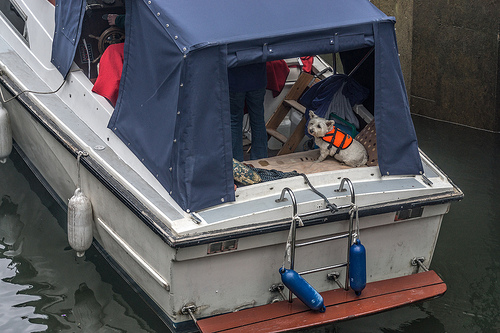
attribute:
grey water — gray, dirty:
[452, 230, 492, 310]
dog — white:
[311, 116, 372, 168]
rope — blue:
[346, 200, 363, 232]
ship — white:
[0, 1, 459, 329]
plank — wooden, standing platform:
[191, 264, 454, 332]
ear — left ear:
[323, 117, 335, 131]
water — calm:
[1, 220, 70, 331]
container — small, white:
[67, 186, 90, 257]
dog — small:
[311, 114, 370, 172]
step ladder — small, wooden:
[268, 76, 324, 152]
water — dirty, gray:
[18, 258, 65, 324]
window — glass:
[0, 2, 37, 44]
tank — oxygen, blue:
[281, 261, 333, 321]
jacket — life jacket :
[319, 125, 356, 155]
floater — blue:
[315, 225, 405, 309]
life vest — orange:
[320, 126, 352, 157]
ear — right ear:
[307, 111, 317, 122]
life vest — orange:
[318, 124, 353, 150]